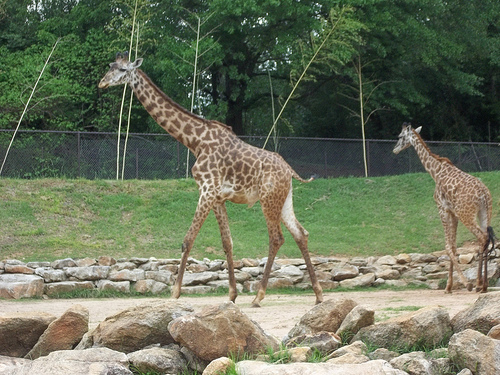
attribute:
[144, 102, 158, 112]
spot — brown 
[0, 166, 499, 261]
grass — dry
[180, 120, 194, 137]
spot — brown 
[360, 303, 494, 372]
rock — large, natural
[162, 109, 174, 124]
spot — brown 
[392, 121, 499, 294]
giraffe — young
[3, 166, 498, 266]
slope — green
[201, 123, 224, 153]
spot — brown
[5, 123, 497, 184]
fence — metal 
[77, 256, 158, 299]
stones — arranged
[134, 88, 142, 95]
spot — brown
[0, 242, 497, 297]
rock wall — low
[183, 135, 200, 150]
spot — brown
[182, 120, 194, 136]
spot — brown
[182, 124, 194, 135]
spot — brown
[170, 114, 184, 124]
spot — brown 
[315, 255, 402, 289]
stone — blocks 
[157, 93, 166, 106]
spot — brown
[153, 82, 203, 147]
spot — brown 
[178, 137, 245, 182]
spot — brown 